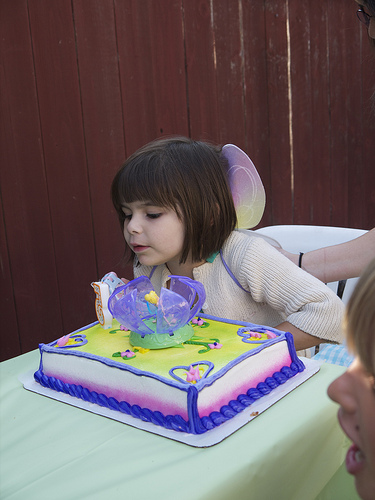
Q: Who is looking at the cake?
A: The girl.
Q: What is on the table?
A: A cake.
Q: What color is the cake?
A: Blue, white, yellow, and pink.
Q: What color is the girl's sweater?
A: Tan.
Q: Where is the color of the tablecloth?
A: Light green.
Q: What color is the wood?
A: Brown.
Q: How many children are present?
A: Two.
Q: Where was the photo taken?
A: At a party.